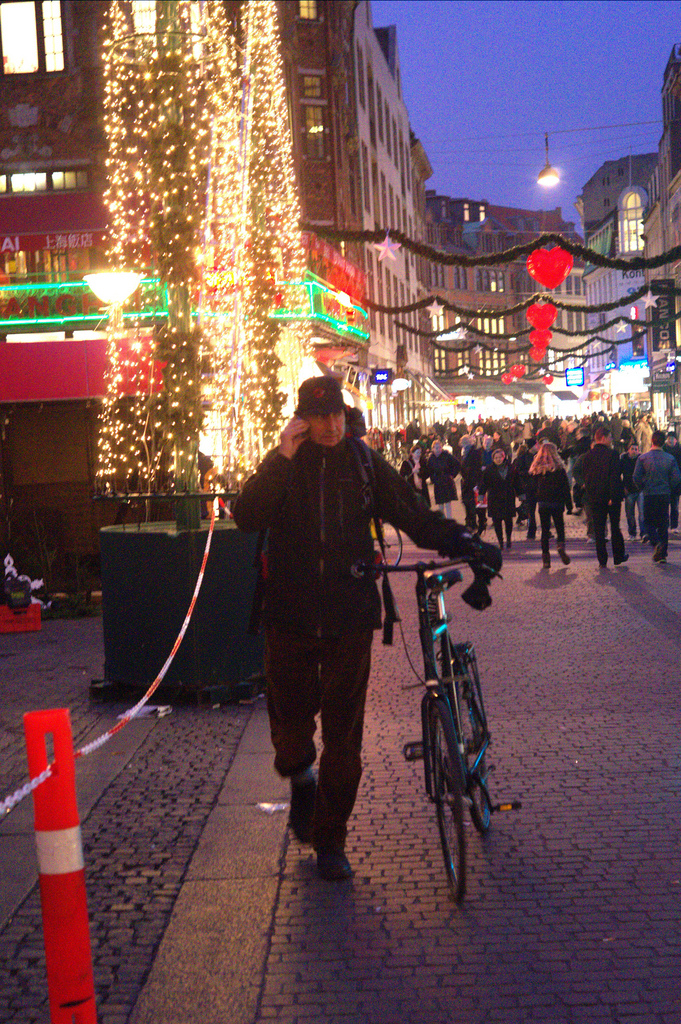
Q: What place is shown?
A: It is a sidewalk.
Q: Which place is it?
A: It is a sidewalk.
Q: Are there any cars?
A: No, there are no cars.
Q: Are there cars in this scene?
A: No, there are no cars.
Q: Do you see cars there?
A: No, there are no cars.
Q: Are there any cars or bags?
A: No, there are no cars or bags.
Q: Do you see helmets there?
A: No, there are no helmets.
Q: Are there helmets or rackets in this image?
A: No, there are no helmets or rackets.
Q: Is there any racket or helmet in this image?
A: No, there are no helmets or rackets.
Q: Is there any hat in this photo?
A: Yes, there is a hat.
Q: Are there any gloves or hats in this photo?
A: Yes, there is a hat.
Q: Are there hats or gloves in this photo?
A: Yes, there is a hat.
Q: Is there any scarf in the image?
A: No, there are no scarves.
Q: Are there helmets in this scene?
A: No, there are no helmets.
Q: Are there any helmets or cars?
A: No, there are no helmets or cars.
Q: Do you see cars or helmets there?
A: No, there are no helmets or cars.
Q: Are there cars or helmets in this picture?
A: No, there are no helmets or cars.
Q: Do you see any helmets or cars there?
A: No, there are no helmets or cars.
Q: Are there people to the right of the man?
A: Yes, there is a person to the right of the man.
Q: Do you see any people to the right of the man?
A: Yes, there is a person to the right of the man.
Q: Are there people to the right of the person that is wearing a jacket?
A: Yes, there is a person to the right of the man.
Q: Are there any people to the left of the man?
A: No, the person is to the right of the man.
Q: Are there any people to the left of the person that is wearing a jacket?
A: No, the person is to the right of the man.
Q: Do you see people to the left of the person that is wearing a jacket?
A: No, the person is to the right of the man.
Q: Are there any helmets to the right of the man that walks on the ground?
A: No, there is a person to the right of the man.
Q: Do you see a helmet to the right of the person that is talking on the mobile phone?
A: No, there is a person to the right of the man.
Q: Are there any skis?
A: No, there are no skis.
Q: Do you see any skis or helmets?
A: No, there are no skis or helmets.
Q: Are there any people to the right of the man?
A: Yes, there is a person to the right of the man.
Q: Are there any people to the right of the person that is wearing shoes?
A: Yes, there is a person to the right of the man.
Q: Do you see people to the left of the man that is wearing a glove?
A: No, the person is to the right of the man.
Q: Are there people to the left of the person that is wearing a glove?
A: No, the person is to the right of the man.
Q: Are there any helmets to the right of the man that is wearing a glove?
A: No, there is a person to the right of the man.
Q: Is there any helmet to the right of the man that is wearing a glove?
A: No, there is a person to the right of the man.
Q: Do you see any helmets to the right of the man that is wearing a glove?
A: No, there is a person to the right of the man.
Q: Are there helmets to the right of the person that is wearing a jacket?
A: No, there is a person to the right of the man.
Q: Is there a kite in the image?
A: No, there are no kites.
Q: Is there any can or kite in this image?
A: No, there are no kites or cans.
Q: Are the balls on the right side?
A: Yes, the balls are on the right of the image.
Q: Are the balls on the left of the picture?
A: No, the balls are on the right of the image.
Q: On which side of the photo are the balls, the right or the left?
A: The balls are on the right of the image.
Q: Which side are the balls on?
A: The balls are on the right of the image.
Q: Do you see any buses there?
A: No, there are no buses.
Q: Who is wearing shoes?
A: The man is wearing shoes.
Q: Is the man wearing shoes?
A: Yes, the man is wearing shoes.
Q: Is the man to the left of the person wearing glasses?
A: No, the man is wearing shoes.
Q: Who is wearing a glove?
A: The man is wearing a glove.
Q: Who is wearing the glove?
A: The man is wearing a glove.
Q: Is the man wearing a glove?
A: Yes, the man is wearing a glove.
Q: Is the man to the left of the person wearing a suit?
A: No, the man is wearing a glove.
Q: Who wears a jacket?
A: The man wears a jacket.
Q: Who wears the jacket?
A: The man wears a jacket.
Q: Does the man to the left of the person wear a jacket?
A: Yes, the man wears a jacket.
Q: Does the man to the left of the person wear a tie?
A: No, the man wears a jacket.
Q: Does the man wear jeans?
A: Yes, the man wears jeans.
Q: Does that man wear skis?
A: No, the man wears jeans.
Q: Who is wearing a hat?
A: The man is wearing a hat.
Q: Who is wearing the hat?
A: The man is wearing a hat.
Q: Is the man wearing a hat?
A: Yes, the man is wearing a hat.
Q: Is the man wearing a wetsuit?
A: No, the man is wearing a hat.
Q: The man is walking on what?
A: The man is walking on the ground.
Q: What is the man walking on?
A: The man is walking on the ground.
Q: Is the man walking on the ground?
A: Yes, the man is walking on the ground.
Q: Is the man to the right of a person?
A: No, the man is to the left of a person.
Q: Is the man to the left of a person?
A: Yes, the man is to the left of a person.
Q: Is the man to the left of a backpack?
A: No, the man is to the left of a person.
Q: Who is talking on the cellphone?
A: The man is talking on the cellphone.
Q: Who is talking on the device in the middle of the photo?
A: The man is talking on the cellphone.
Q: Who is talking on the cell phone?
A: The man is talking on the cellphone.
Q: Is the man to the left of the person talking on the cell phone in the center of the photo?
A: Yes, the man is talking on the cellphone.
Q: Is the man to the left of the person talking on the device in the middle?
A: Yes, the man is talking on the cellphone.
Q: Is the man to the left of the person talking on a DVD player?
A: No, the man is talking on the cellphone.